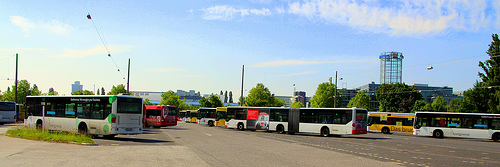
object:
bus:
[24, 95, 145, 140]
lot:
[0, 121, 499, 166]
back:
[111, 95, 144, 135]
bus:
[224, 106, 367, 137]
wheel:
[320, 125, 330, 137]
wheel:
[276, 124, 285, 134]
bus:
[413, 111, 500, 141]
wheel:
[433, 129, 444, 139]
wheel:
[492, 132, 500, 141]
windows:
[270, 108, 353, 125]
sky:
[0, 1, 499, 103]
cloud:
[184, 0, 500, 39]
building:
[378, 52, 404, 84]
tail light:
[111, 117, 116, 123]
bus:
[145, 105, 178, 128]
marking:
[102, 124, 109, 134]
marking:
[109, 95, 117, 104]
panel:
[246, 110, 259, 120]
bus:
[367, 112, 416, 134]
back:
[161, 105, 178, 125]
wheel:
[78, 121, 88, 136]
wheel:
[35, 118, 42, 132]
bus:
[215, 107, 227, 127]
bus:
[196, 108, 217, 127]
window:
[117, 96, 143, 114]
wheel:
[381, 126, 391, 134]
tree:
[309, 82, 344, 108]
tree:
[238, 83, 285, 107]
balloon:
[427, 66, 433, 71]